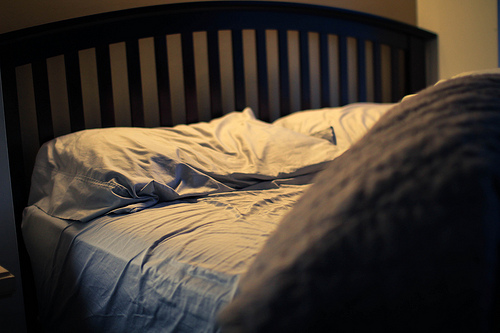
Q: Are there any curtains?
A: No, there are no curtains.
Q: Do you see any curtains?
A: No, there are no curtains.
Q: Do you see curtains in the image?
A: No, there are no curtains.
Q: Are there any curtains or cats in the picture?
A: No, there are no curtains or cats.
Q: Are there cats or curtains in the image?
A: No, there are no curtains or cats.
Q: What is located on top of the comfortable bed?
A: The comforter is on top of the bed.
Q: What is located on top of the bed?
A: The comforter is on top of the bed.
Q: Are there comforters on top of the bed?
A: Yes, there is a comforter on top of the bed.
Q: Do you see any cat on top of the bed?
A: No, there is a comforter on top of the bed.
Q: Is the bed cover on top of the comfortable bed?
A: Yes, the bed cover is on top of the bed.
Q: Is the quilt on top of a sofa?
A: No, the quilt is on top of the bed.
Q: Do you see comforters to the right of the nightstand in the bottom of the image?
A: Yes, there is a comforter to the right of the nightstand.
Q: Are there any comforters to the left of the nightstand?
A: No, the comforter is to the right of the nightstand.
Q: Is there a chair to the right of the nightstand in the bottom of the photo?
A: No, there is a comforter to the right of the nightstand.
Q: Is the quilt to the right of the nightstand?
A: Yes, the quilt is to the right of the nightstand.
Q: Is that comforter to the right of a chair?
A: No, the comforter is to the right of the nightstand.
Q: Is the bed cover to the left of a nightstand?
A: No, the bed cover is to the right of a nightstand.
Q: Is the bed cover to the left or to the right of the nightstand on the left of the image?
A: The bed cover is to the right of the nightstand.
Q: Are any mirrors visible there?
A: No, there are no mirrors.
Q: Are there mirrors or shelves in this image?
A: No, there are no mirrors or shelves.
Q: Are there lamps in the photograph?
A: No, there are no lamps.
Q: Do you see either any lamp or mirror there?
A: No, there are no lamps or mirrors.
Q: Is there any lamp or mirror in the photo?
A: No, there are no lamps or mirrors.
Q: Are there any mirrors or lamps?
A: No, there are no lamps or mirrors.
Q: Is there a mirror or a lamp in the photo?
A: No, there are no lamps or mirrors.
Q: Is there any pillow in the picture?
A: Yes, there is a pillow.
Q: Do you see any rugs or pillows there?
A: Yes, there is a pillow.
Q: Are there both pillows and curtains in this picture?
A: No, there is a pillow but no curtains.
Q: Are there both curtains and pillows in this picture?
A: No, there is a pillow but no curtains.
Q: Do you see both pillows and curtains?
A: No, there is a pillow but no curtains.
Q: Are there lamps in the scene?
A: No, there are no lamps.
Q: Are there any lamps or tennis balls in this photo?
A: No, there are no lamps or tennis balls.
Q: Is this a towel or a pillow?
A: This is a pillow.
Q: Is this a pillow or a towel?
A: This is a pillow.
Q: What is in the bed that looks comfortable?
A: The pillow is in the bed.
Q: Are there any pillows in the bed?
A: Yes, there is a pillow in the bed.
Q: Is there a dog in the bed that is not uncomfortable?
A: No, there is a pillow in the bed.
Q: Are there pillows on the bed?
A: Yes, there is a pillow on the bed.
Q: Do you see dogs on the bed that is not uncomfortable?
A: No, there is a pillow on the bed.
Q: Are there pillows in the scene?
A: Yes, there is a pillow.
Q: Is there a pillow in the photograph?
A: Yes, there is a pillow.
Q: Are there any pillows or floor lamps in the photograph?
A: Yes, there is a pillow.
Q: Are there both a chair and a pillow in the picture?
A: No, there is a pillow but no chairs.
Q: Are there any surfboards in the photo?
A: No, there are no surfboards.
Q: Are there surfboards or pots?
A: No, there are no surfboards or pots.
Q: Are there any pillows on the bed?
A: Yes, there is a pillow on the bed.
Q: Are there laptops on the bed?
A: No, there is a pillow on the bed.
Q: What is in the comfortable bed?
A: The pillow is in the bed.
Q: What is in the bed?
A: The pillow is in the bed.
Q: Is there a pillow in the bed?
A: Yes, there is a pillow in the bed.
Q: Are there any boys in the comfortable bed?
A: No, there is a pillow in the bed.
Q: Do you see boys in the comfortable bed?
A: No, there is a pillow in the bed.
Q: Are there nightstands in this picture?
A: Yes, there is a nightstand.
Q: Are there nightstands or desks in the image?
A: Yes, there is a nightstand.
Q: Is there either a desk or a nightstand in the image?
A: Yes, there is a nightstand.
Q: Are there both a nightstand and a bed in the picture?
A: Yes, there are both a nightstand and a bed.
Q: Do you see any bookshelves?
A: No, there are no bookshelves.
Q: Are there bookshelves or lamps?
A: No, there are no bookshelves or lamps.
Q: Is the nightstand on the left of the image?
A: Yes, the nightstand is on the left of the image.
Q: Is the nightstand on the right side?
A: No, the nightstand is on the left of the image.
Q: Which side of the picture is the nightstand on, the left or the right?
A: The nightstand is on the left of the image.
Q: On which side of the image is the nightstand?
A: The nightstand is on the left of the image.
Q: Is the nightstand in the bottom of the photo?
A: Yes, the nightstand is in the bottom of the image.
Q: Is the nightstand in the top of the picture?
A: No, the nightstand is in the bottom of the image.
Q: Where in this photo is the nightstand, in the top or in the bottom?
A: The nightstand is in the bottom of the image.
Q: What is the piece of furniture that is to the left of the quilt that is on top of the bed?
A: The piece of furniture is a nightstand.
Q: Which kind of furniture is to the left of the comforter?
A: The piece of furniture is a nightstand.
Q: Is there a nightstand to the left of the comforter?
A: Yes, there is a nightstand to the left of the comforter.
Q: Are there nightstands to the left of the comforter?
A: Yes, there is a nightstand to the left of the comforter.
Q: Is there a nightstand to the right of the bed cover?
A: No, the nightstand is to the left of the bed cover.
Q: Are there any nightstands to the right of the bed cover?
A: No, the nightstand is to the left of the bed cover.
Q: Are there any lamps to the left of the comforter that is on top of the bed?
A: No, there is a nightstand to the left of the comforter.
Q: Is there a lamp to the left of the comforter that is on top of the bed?
A: No, there is a nightstand to the left of the comforter.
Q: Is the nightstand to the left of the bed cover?
A: Yes, the nightstand is to the left of the bed cover.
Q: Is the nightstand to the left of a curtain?
A: No, the nightstand is to the left of the bed cover.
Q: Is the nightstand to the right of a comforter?
A: No, the nightstand is to the left of a comforter.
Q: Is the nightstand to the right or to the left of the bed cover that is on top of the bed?
A: The nightstand is to the left of the comforter.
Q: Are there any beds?
A: Yes, there is a bed.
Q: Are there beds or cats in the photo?
A: Yes, there is a bed.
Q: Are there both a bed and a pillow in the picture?
A: Yes, there are both a bed and a pillow.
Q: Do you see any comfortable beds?
A: Yes, there is a comfortable bed.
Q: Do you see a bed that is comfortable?
A: Yes, there is a bed that is comfortable.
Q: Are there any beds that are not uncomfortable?
A: Yes, there is an comfortable bed.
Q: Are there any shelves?
A: No, there are no shelves.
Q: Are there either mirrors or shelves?
A: No, there are no shelves or mirrors.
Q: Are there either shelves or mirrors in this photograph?
A: No, there are no shelves or mirrors.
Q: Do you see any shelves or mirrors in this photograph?
A: No, there are no shelves or mirrors.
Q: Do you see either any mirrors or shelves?
A: No, there are no shelves or mirrors.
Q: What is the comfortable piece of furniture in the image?
A: The piece of furniture is a bed.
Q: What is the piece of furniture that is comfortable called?
A: The piece of furniture is a bed.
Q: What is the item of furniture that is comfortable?
A: The piece of furniture is a bed.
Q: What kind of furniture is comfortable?
A: The furniture is a bed.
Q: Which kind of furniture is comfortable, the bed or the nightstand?
A: The bed is comfortable.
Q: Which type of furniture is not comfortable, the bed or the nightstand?
A: The nightstand is not comfortable.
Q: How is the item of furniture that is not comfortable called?
A: The piece of furniture is a nightstand.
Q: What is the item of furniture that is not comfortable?
A: The piece of furniture is a nightstand.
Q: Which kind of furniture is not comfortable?
A: The furniture is a nightstand.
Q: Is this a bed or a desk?
A: This is a bed.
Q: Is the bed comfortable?
A: Yes, the bed is comfortable.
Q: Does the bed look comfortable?
A: Yes, the bed is comfortable.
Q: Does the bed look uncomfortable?
A: No, the bed is comfortable.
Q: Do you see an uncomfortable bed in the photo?
A: No, there is a bed but it is comfortable.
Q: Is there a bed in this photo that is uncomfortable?
A: No, there is a bed but it is comfortable.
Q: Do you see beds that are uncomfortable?
A: No, there is a bed but it is comfortable.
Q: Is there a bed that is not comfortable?
A: No, there is a bed but it is comfortable.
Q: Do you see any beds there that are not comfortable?
A: No, there is a bed but it is comfortable.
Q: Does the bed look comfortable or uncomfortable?
A: The bed is comfortable.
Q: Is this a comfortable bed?
A: Yes, this is a comfortable bed.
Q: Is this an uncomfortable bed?
A: No, this is a comfortable bed.